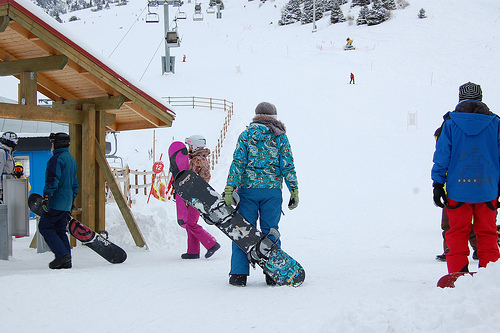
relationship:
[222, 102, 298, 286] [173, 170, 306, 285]
person carrying snowboard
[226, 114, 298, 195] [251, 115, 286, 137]
parka has hood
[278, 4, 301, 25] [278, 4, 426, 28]
pine part of cluster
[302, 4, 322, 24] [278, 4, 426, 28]
pine part of cluster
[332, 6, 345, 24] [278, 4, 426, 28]
pine part of cluster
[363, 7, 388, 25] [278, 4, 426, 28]
pine part of cluster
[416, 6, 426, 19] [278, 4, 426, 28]
pine part of cluster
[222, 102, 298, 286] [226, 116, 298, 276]
person wearing outfit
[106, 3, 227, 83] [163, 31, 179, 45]
chairlift has seat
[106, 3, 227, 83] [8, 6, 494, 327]
chairlift going to top of slope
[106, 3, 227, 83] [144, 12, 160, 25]
chairlift has seat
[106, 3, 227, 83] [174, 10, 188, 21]
chairlift has seat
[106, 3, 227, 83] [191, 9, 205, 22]
chairlift has seat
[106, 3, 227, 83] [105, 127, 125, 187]
chairlift has seat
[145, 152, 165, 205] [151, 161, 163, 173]
sign has number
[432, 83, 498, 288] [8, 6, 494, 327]
man watching slope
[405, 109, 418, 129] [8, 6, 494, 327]
marker for slope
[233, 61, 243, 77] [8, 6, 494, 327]
marker for slope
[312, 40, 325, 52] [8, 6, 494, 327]
marker for slope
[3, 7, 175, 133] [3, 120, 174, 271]
roof for break area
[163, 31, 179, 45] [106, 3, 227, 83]
seat going up chairlift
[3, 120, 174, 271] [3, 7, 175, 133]
break area has roof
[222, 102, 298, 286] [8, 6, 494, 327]
person watching slope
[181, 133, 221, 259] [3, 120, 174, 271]
woman going to break area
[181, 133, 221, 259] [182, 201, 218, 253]
woman wearing pants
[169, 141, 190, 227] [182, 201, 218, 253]
snowboard matching pants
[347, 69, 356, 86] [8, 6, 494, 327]
man on top of slope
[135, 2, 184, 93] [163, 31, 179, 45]
wire supporting seat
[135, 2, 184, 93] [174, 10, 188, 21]
wire supporting seat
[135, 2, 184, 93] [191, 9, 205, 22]
wire supporting seat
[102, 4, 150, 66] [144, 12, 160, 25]
wire supporting seat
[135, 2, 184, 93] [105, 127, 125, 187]
wire supporting seat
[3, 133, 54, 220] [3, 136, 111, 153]
building has roof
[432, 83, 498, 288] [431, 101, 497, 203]
man wearing jacket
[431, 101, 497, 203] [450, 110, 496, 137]
jacket has hood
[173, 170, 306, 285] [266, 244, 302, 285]
snowboard has design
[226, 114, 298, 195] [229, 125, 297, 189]
parka has design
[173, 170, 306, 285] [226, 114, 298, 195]
snowboard matches parka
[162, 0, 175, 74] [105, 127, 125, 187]
pole supporting seat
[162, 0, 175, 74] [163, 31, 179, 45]
pole supporting seat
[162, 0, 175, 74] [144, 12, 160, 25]
pole supporting seat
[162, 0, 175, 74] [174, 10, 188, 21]
pole supporting seat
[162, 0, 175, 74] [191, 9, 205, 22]
pole supporting seat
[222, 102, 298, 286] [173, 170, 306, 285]
person holding snowboard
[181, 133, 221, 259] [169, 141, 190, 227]
woman carrying snowboard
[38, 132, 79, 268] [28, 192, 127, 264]
person carrying snowboard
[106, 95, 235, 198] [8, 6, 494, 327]
fencing located on top of slope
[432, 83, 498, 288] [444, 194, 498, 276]
man wearing pants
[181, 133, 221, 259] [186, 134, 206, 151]
woman wearing helmet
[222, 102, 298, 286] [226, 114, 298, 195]
person wearing parka